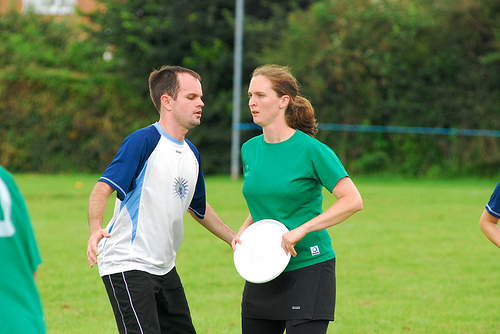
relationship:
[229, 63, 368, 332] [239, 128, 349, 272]
she wearing shirt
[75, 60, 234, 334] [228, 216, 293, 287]
man playing frisbee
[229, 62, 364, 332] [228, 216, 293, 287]
lady playing frisbee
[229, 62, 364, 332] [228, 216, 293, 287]
lady holding frisbee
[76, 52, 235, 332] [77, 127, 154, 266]
man has arms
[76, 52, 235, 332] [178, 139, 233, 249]
man has arms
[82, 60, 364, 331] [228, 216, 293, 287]
couple learning frisbee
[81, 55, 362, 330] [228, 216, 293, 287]
people playing frisbee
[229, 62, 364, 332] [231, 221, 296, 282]
lady holding frisbee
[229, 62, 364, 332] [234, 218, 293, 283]
lady playing frisbee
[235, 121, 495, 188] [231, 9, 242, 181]
net attached to pole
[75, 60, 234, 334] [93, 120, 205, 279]
man wearing shirt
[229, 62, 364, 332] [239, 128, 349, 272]
lady wearing shirt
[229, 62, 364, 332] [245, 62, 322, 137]
lady with hair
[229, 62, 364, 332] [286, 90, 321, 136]
lady in a pony tail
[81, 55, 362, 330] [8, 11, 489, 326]
people in a park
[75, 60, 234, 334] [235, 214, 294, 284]
man trying to grab a frisbee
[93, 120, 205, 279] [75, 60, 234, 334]
shirt on man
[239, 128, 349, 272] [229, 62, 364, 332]
shirt on lady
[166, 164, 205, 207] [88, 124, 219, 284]
image on shirt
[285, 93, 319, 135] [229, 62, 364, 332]
pony tail on lady